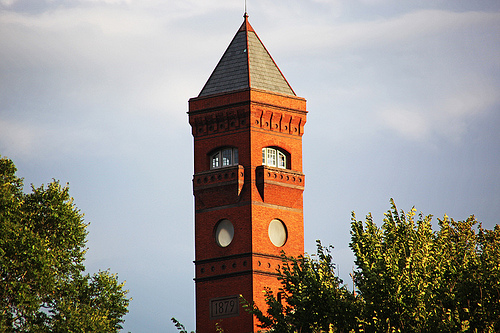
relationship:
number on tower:
[208, 296, 241, 321] [188, 3, 310, 333]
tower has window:
[188, 3, 310, 333] [207, 146, 240, 175]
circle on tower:
[267, 218, 289, 249] [188, 3, 310, 333]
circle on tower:
[212, 217, 235, 246] [188, 3, 310, 333]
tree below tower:
[241, 186, 499, 333] [188, 3, 310, 333]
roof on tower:
[197, 17, 296, 98] [188, 3, 310, 333]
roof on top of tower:
[197, 17, 296, 98] [188, 3, 310, 333]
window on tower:
[207, 146, 240, 175] [188, 3, 310, 333]